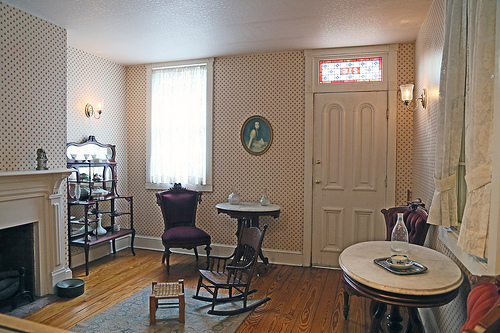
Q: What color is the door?
A: Cream.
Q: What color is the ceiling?
A: White.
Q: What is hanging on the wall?
A: A painting.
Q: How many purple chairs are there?
A: One.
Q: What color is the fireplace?
A: White and black.